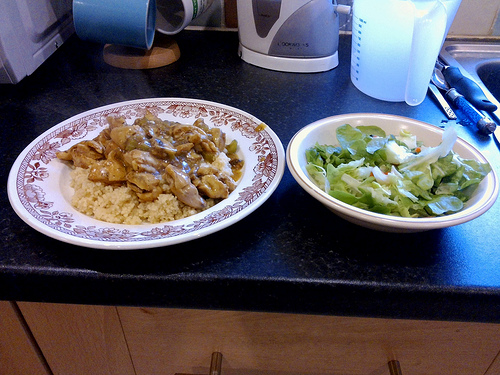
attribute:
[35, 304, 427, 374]
cabinets — Wood-look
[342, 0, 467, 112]
cup — plastic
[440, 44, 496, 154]
sink — Stainless steel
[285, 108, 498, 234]
bowl — white, circular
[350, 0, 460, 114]
measuring container — clear, plastic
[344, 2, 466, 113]
jug — measuring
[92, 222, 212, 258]
plate — white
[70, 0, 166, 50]
cup — blue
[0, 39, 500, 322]
counter — black